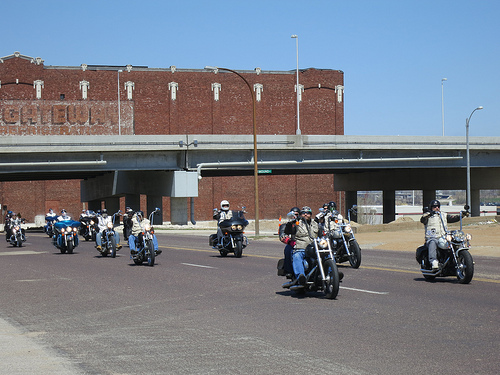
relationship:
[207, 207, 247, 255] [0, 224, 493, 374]
bike on a road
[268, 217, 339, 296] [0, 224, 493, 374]
bike on a road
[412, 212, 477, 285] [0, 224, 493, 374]
bike on a road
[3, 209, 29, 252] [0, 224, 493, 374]
bike on a road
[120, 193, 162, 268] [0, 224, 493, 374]
bike on a road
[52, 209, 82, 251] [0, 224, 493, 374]
bike on a road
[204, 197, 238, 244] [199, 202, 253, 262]
person on bike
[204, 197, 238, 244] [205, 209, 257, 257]
person riding motorcycle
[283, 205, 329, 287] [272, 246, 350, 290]
person riding on a motorcycle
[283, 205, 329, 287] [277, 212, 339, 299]
person riding motorcycle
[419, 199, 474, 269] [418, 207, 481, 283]
person on bike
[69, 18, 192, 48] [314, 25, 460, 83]
clouds in sky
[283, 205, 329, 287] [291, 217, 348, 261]
person on bike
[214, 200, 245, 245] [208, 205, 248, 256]
man on bike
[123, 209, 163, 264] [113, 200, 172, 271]
person on motorcycle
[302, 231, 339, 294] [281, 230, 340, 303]
front of bike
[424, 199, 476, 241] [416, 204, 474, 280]
handlebars of bike